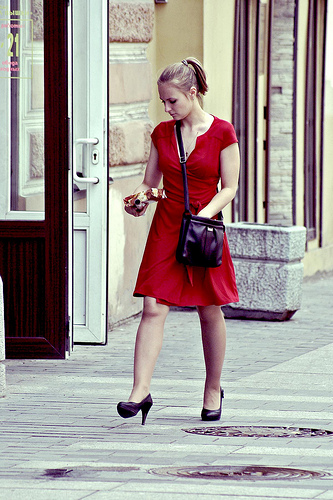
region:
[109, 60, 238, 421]
woman in red dress and black shoes walking down sidewalk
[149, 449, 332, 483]
man hole cover on sidewalk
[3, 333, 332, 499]
grey sidewalk where a woman is walking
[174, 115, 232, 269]
woman with black purse opened and her hand is in it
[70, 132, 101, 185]
white handle of a door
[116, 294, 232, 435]
woman is wearing black high heal shoes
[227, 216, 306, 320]
a stone garbage can on street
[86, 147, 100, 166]
old lock to put key into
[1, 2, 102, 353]
opened door to a business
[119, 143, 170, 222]
woman is holding something in her left hand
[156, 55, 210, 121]
the girl has a brown ponytail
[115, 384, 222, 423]
the girl is wearing black heels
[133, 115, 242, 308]
the lady is wearing a red wrap around dress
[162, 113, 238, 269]
the girl has an over the shoulder bag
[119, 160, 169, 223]
the girl has paper in her hand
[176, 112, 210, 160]
the girl has a gold chain on her neck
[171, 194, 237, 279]
the woman has her hand in the bag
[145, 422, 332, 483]
manhole covers are in the sidewalk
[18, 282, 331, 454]
the sidewalk is tiled cement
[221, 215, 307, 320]
an empty cement planter is on the sidewalk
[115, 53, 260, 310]
a woman in a red dress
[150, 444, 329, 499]
a man hole cover on the sidewalk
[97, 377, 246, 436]
black high heeled shoes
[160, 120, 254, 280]
a black purse with a hand in it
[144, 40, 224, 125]
girl with her hair in a poneytail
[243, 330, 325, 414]
a paved side walk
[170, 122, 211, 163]
a silver cross necklace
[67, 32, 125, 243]
a door with a white handle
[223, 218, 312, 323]
a cement trash recepticle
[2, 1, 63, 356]
a brown wooden door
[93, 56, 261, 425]
lady walking down the street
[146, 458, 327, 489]
manhole cover in the sidewalk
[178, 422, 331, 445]
manhole cover in the sidewalk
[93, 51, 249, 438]
lady wearing a red dress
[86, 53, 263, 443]
lady carrying a black purse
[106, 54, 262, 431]
lady with blonde hair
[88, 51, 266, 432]
lady with hair in pony tail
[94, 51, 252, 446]
lady carrying a wrapped package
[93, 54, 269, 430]
lady wearing high heels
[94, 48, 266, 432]
lady wearing black shoes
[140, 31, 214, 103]
Girls hair is in a pony tail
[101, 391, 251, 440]
Girl wearing black heals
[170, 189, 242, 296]
Girl has black purse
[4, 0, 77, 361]
Door with dark wood grain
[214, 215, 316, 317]
Concrete trash can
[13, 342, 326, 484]
Stone walk way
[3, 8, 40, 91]
Yellow and pink writing on door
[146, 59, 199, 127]
Girl looking at object in hand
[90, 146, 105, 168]
Old fashion looking key hole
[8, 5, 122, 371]
Doors are open